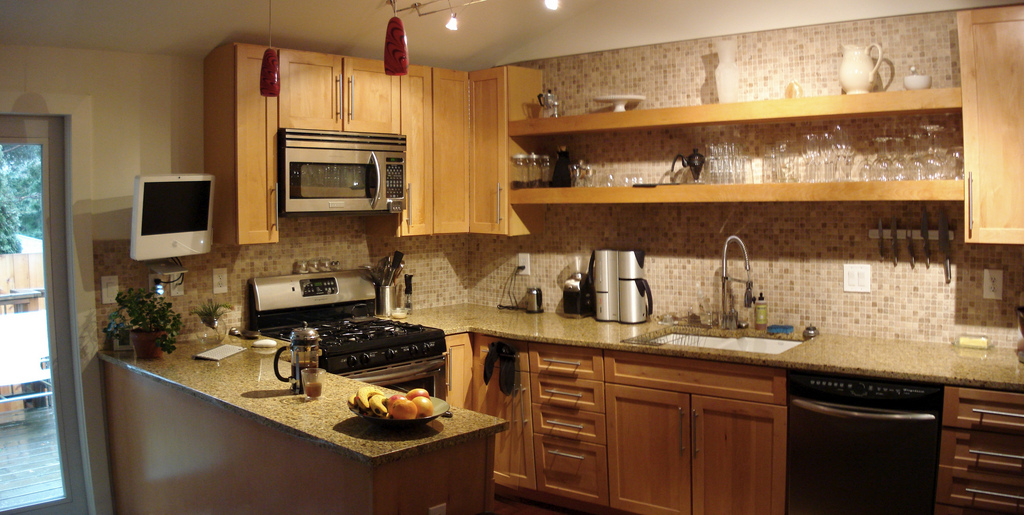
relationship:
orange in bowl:
[385, 394, 418, 420] [345, 394, 452, 431]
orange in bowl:
[413, 392, 439, 419] [345, 394, 452, 431]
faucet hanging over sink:
[714, 230, 756, 330] [636, 323, 807, 362]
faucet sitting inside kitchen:
[714, 230, 756, 330] [3, 3, 993, 511]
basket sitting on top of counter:
[340, 387, 457, 429] [94, 333, 511, 467]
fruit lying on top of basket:
[389, 394, 420, 421] [340, 387, 457, 429]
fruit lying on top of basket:
[407, 390, 434, 416] [340, 387, 457, 429]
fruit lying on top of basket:
[404, 379, 433, 399] [340, 387, 457, 429]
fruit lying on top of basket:
[366, 392, 392, 419] [340, 387, 457, 429]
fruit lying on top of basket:
[353, 383, 386, 416] [340, 387, 457, 429]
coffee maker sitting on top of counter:
[582, 243, 658, 328] [389, 299, 994, 392]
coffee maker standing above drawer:
[582, 243, 658, 328] [532, 344, 600, 383]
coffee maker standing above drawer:
[582, 243, 658, 328] [532, 374, 604, 414]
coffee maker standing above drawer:
[582, 243, 658, 328] [528, 398, 608, 446]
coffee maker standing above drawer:
[582, 243, 658, 328] [526, 424, 609, 505]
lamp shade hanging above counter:
[379, 16, 410, 81] [91, 296, 993, 469]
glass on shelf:
[918, 108, 951, 175] [486, 4, 1022, 264]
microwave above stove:
[273, 122, 405, 222] [228, 261, 458, 409]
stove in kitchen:
[228, 261, 458, 409] [72, 50, 1014, 498]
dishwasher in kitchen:
[768, 357, 924, 509] [94, 5, 1019, 503]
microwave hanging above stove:
[273, 122, 405, 222] [228, 261, 458, 409]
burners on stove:
[274, 317, 452, 380] [229, 261, 459, 409]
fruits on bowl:
[352, 380, 441, 420] [337, 402, 467, 442]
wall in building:
[87, 84, 172, 169] [6, 10, 1018, 508]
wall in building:
[661, 255, 705, 310] [6, 10, 1018, 508]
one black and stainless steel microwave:
[264, 107, 414, 278] [273, 122, 405, 222]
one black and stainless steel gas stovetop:
[255, 265, 454, 406] [330, 287, 372, 348]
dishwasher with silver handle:
[767, 357, 923, 509] [776, 405, 937, 427]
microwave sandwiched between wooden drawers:
[273, 122, 405, 222] [229, 233, 450, 246]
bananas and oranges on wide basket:
[346, 356, 448, 417] [340, 387, 457, 429]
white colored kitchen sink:
[594, 243, 849, 408] [681, 328, 755, 359]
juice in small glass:
[255, 300, 336, 461] [290, 356, 316, 383]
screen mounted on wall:
[91, 131, 251, 317] [73, 246, 110, 324]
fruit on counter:
[353, 383, 436, 419] [146, 332, 509, 471]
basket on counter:
[340, 387, 457, 429] [146, 332, 509, 471]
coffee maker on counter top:
[581, 243, 657, 328] [452, 322, 682, 351]